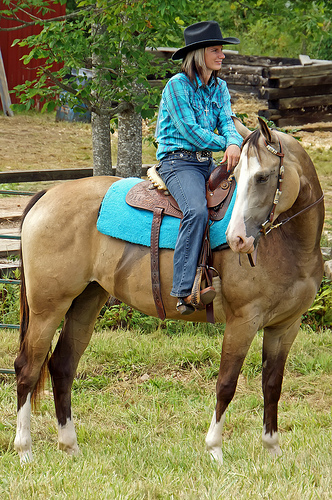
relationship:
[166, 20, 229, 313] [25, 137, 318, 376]
woman on horse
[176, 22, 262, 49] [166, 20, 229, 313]
hat on woman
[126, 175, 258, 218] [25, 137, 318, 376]
saddle on horse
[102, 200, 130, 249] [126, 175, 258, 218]
blue banket under saddle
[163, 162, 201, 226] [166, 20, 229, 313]
jeans on woman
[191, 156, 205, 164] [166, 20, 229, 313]
silver buckle on woman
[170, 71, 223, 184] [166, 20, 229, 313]
blue shirt on woman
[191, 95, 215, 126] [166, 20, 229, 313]
cross necklace on woman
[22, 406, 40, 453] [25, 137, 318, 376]
white stocking on horse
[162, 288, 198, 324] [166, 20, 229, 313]
brown boot on woman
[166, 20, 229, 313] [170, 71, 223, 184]
woman in blue shirt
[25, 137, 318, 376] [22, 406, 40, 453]
horse with white stocking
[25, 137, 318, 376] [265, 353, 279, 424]
horse with black markings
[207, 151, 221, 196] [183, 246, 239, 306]
saddle strap to stirrup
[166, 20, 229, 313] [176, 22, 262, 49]
woman in hat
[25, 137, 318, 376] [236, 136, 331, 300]
horse with head turned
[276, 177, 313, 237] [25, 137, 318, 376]
bridle on horse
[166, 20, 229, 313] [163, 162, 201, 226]
woman in jeans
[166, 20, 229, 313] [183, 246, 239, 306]
woman and stirrup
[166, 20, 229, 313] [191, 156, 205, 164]
woman in silver buckle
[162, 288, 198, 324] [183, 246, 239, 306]
brown boot in stirrup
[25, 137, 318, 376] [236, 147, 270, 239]
horse with white markings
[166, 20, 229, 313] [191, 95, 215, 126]
woman in cross necklace